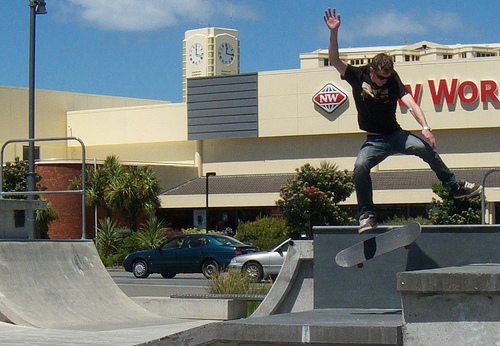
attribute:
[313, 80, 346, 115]
sign — red, white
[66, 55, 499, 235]
tan building — white